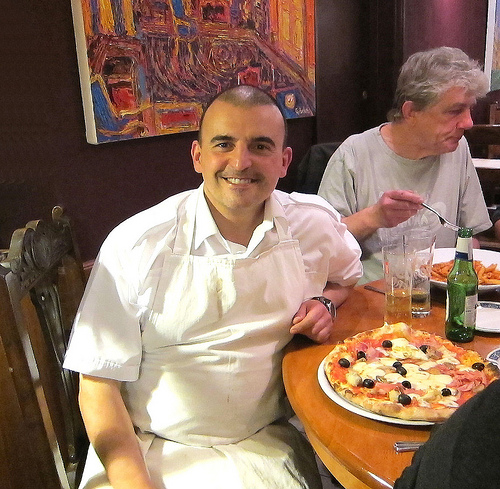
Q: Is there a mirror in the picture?
A: No, there are no mirrors.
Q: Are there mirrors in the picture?
A: No, there are no mirrors.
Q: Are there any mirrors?
A: No, there are no mirrors.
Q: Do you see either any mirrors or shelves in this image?
A: No, there are no mirrors or shelves.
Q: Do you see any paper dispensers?
A: No, there are no paper dispensers.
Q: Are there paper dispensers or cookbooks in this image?
A: No, there are no paper dispensers or cookbooks.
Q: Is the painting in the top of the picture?
A: Yes, the painting is in the top of the image.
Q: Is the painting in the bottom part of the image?
A: No, the painting is in the top of the image.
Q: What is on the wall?
A: The painting is on the wall.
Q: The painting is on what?
A: The painting is on the wall.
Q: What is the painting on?
A: The painting is on the wall.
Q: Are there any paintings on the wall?
A: Yes, there is a painting on the wall.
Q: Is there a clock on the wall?
A: No, there is a painting on the wall.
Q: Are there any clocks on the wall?
A: No, there is a painting on the wall.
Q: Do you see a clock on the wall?
A: No, there is a painting on the wall.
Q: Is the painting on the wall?
A: Yes, the painting is on the wall.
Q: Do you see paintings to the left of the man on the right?
A: Yes, there is a painting to the left of the man.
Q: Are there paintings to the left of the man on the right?
A: Yes, there is a painting to the left of the man.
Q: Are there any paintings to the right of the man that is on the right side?
A: No, the painting is to the left of the man.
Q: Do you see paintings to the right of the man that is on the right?
A: No, the painting is to the left of the man.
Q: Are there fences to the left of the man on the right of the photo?
A: No, there is a painting to the left of the man.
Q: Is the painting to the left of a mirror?
A: No, the painting is to the left of a man.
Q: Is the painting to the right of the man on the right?
A: No, the painting is to the left of the man.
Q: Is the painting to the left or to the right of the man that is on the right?
A: The painting is to the left of the man.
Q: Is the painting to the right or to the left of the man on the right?
A: The painting is to the left of the man.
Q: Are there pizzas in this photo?
A: Yes, there is a pizza.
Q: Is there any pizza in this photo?
A: Yes, there is a pizza.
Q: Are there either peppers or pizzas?
A: Yes, there is a pizza.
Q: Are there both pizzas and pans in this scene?
A: No, there is a pizza but no pans.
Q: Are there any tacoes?
A: No, there are no tacoes.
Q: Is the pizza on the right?
A: Yes, the pizza is on the right of the image.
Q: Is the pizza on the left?
A: No, the pizza is on the right of the image.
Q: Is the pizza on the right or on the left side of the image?
A: The pizza is on the right of the image.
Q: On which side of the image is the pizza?
A: The pizza is on the right of the image.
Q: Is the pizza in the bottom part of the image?
A: Yes, the pizza is in the bottom of the image.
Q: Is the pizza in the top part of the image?
A: No, the pizza is in the bottom of the image.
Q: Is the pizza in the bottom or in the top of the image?
A: The pizza is in the bottom of the image.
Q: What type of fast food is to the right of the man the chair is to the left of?
A: The food is a pizza.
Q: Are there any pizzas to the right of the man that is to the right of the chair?
A: Yes, there is a pizza to the right of the man.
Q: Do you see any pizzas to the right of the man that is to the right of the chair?
A: Yes, there is a pizza to the right of the man.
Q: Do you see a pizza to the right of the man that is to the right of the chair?
A: Yes, there is a pizza to the right of the man.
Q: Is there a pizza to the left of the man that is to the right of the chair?
A: No, the pizza is to the right of the man.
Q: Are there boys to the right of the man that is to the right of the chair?
A: No, there is a pizza to the right of the man.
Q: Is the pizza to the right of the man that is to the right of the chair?
A: Yes, the pizza is to the right of the man.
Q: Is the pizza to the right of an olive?
A: No, the pizza is to the right of the man.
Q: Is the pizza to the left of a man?
A: No, the pizza is to the right of a man.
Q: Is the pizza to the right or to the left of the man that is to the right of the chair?
A: The pizza is to the right of the man.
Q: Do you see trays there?
A: No, there are no trays.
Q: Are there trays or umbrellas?
A: No, there are no trays or umbrellas.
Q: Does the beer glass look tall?
A: Yes, the glass is tall.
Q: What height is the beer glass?
A: The glass is tall.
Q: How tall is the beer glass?
A: The glass is tall.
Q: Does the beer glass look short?
A: No, the glass is tall.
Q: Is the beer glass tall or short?
A: The glass is tall.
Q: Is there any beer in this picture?
A: Yes, there is beer.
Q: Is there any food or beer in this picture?
A: Yes, there is beer.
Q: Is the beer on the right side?
A: Yes, the beer is on the right of the image.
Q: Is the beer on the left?
A: No, the beer is on the right of the image.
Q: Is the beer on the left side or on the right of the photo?
A: The beer is on the right of the image.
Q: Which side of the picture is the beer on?
A: The beer is on the right of the image.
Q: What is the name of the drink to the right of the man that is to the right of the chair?
A: The drink is beer.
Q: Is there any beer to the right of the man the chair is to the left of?
A: Yes, there is beer to the right of the man.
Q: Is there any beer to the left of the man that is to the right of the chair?
A: No, the beer is to the right of the man.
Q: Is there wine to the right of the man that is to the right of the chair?
A: No, there is beer to the right of the man.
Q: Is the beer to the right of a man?
A: Yes, the beer is to the right of a man.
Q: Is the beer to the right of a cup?
A: No, the beer is to the right of a man.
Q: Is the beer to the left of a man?
A: No, the beer is to the right of a man.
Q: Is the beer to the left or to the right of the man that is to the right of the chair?
A: The beer is to the right of the man.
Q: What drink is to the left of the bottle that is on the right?
A: The drink is beer.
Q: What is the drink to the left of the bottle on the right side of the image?
A: The drink is beer.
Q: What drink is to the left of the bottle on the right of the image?
A: The drink is beer.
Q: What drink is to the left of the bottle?
A: The drink is beer.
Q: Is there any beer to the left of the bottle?
A: Yes, there is beer to the left of the bottle.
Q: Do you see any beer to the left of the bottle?
A: Yes, there is beer to the left of the bottle.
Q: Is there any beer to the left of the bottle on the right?
A: Yes, there is beer to the left of the bottle.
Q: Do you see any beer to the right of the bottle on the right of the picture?
A: No, the beer is to the left of the bottle.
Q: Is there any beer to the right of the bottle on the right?
A: No, the beer is to the left of the bottle.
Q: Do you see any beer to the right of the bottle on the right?
A: No, the beer is to the left of the bottle.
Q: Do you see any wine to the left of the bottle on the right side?
A: No, there is beer to the left of the bottle.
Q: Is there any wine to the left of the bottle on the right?
A: No, there is beer to the left of the bottle.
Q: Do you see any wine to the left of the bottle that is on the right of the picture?
A: No, there is beer to the left of the bottle.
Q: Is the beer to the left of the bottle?
A: Yes, the beer is to the left of the bottle.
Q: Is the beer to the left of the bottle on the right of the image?
A: Yes, the beer is to the left of the bottle.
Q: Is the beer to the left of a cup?
A: No, the beer is to the left of the bottle.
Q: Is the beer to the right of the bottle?
A: No, the beer is to the left of the bottle.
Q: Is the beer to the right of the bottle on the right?
A: No, the beer is to the left of the bottle.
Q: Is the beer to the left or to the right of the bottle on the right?
A: The beer is to the left of the bottle.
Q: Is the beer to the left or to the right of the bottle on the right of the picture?
A: The beer is to the left of the bottle.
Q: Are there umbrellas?
A: No, there are no umbrellas.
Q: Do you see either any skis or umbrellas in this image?
A: No, there are no umbrellas or skis.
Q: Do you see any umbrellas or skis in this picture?
A: No, there are no umbrellas or skis.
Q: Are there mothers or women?
A: No, there are no women or mothers.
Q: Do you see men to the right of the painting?
A: Yes, there is a man to the right of the painting.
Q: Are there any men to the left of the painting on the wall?
A: No, the man is to the right of the painting.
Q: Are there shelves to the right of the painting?
A: No, there is a man to the right of the painting.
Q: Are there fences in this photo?
A: No, there are no fences.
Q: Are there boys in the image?
A: No, there are no boys.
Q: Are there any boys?
A: No, there are no boys.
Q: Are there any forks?
A: Yes, there is a fork.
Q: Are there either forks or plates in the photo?
A: Yes, there is a fork.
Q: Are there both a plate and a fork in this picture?
A: Yes, there are both a fork and a plate.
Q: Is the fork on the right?
A: Yes, the fork is on the right of the image.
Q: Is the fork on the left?
A: No, the fork is on the right of the image.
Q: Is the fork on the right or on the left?
A: The fork is on the right of the image.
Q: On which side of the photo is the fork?
A: The fork is on the right of the image.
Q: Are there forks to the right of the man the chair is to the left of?
A: Yes, there is a fork to the right of the man.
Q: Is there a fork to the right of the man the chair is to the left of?
A: Yes, there is a fork to the right of the man.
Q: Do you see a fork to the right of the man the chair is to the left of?
A: Yes, there is a fork to the right of the man.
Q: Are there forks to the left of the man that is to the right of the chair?
A: No, the fork is to the right of the man.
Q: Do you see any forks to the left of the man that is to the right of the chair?
A: No, the fork is to the right of the man.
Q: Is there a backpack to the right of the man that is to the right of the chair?
A: No, there is a fork to the right of the man.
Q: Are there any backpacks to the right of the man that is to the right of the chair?
A: No, there is a fork to the right of the man.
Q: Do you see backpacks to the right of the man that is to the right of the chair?
A: No, there is a fork to the right of the man.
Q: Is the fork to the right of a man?
A: Yes, the fork is to the right of a man.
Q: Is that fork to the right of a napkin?
A: No, the fork is to the right of a man.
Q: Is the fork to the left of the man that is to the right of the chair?
A: No, the fork is to the right of the man.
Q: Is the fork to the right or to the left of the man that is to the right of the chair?
A: The fork is to the right of the man.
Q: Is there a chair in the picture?
A: Yes, there is a chair.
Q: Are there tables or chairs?
A: Yes, there is a chair.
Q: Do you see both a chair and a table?
A: Yes, there are both a chair and a table.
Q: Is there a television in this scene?
A: No, there are no televisions.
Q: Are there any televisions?
A: No, there are no televisions.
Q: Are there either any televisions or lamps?
A: No, there are no televisions or lamps.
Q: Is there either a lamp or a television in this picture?
A: No, there are no televisions or lamps.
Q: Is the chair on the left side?
A: Yes, the chair is on the left of the image.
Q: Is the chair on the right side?
A: No, the chair is on the left of the image.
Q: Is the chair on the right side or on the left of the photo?
A: The chair is on the left of the image.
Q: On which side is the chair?
A: The chair is on the left of the image.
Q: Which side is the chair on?
A: The chair is on the left of the image.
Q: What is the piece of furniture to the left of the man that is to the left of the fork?
A: The piece of furniture is a chair.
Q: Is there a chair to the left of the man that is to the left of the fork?
A: Yes, there is a chair to the left of the man.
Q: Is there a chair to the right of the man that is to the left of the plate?
A: No, the chair is to the left of the man.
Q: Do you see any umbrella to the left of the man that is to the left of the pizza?
A: No, there is a chair to the left of the man.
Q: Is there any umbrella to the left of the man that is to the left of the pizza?
A: No, there is a chair to the left of the man.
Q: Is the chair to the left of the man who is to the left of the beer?
A: Yes, the chair is to the left of the man.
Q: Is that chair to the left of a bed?
A: No, the chair is to the left of the man.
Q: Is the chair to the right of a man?
A: No, the chair is to the left of a man.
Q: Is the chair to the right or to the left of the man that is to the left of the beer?
A: The chair is to the left of the man.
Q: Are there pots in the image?
A: No, there are no pots.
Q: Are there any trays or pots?
A: No, there are no pots or trays.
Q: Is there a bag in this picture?
A: No, there are no bags.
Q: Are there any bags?
A: No, there are no bags.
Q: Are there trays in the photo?
A: No, there are no trays.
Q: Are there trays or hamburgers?
A: No, there are no trays or hamburgers.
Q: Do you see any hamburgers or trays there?
A: No, there are no trays or hamburgers.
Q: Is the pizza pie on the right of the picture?
A: Yes, the pizza pie is on the right of the image.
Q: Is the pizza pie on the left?
A: No, the pizza pie is on the right of the image.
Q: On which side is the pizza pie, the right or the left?
A: The pizza pie is on the right of the image.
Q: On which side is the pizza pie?
A: The pizza pie is on the right of the image.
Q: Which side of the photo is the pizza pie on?
A: The pizza pie is on the right of the image.